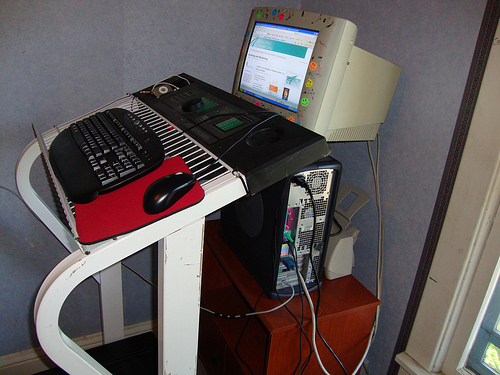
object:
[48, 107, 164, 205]
keyboard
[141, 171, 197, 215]
mouse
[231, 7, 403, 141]
monitor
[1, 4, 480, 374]
wall